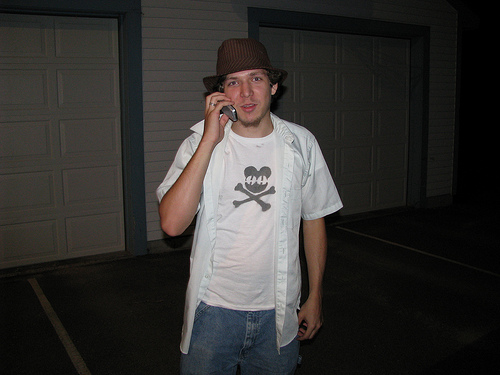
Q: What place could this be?
A: It is a garage.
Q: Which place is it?
A: It is a garage.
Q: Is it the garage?
A: Yes, it is the garage.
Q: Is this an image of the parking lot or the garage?
A: It is showing the garage.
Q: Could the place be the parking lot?
A: No, it is the garage.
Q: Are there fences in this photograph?
A: No, there are no fences.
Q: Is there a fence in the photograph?
A: No, there are no fences.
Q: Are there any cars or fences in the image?
A: No, there are no fences or cars.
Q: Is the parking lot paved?
A: Yes, the parking lot is paved.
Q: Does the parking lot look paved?
A: Yes, the parking lot is paved.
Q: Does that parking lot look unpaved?
A: No, the parking lot is paved.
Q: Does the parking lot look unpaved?
A: No, the parking lot is paved.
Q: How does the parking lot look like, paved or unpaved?
A: The parking lot is paved.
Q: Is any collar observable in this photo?
A: Yes, there is a collar.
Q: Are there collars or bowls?
A: Yes, there is a collar.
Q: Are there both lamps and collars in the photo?
A: No, there is a collar but no lamps.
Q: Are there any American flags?
A: No, there are no American flags.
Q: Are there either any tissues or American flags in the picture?
A: No, there are no American flags or tissues.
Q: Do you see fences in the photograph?
A: No, there are no fences.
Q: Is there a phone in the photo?
A: Yes, there is a phone.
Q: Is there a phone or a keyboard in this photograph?
A: Yes, there is a phone.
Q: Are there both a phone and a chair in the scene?
A: No, there is a phone but no chairs.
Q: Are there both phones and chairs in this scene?
A: No, there is a phone but no chairs.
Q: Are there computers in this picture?
A: No, there are no computers.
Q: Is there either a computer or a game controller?
A: No, there are no computers or game controllers.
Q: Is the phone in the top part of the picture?
A: Yes, the phone is in the top of the image.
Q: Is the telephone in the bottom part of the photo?
A: No, the telephone is in the top of the image.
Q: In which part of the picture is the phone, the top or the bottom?
A: The phone is in the top of the image.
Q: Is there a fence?
A: No, there are no fences.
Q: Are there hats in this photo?
A: Yes, there is a hat.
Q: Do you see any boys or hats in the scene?
A: Yes, there is a hat.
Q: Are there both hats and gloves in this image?
A: No, there is a hat but no gloves.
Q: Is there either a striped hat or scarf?
A: Yes, there is a striped hat.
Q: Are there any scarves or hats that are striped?
A: Yes, the hat is striped.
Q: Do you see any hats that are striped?
A: Yes, there is a striped hat.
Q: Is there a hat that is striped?
A: Yes, there is a hat that is striped.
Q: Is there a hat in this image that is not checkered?
A: Yes, there is a striped hat.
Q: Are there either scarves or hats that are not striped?
A: No, there is a hat but it is striped.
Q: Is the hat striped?
A: Yes, the hat is striped.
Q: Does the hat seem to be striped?
A: Yes, the hat is striped.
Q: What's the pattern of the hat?
A: The hat is striped.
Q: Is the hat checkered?
A: No, the hat is striped.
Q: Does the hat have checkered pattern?
A: No, the hat is striped.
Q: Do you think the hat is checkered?
A: No, the hat is striped.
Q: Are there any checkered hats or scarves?
A: No, there is a hat but it is striped.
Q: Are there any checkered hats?
A: No, there is a hat but it is striped.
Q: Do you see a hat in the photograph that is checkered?
A: No, there is a hat but it is striped.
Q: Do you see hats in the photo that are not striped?
A: No, there is a hat but it is striped.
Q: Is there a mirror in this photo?
A: No, there are no mirrors.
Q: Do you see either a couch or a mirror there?
A: No, there are no mirrors or couches.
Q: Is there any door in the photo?
A: Yes, there are doors.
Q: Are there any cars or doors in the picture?
A: Yes, there are doors.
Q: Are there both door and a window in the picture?
A: No, there are doors but no windows.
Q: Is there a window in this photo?
A: No, there are no windows.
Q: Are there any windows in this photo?
A: No, there are no windows.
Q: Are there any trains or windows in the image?
A: No, there are no windows or trains.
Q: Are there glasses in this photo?
A: No, there are no glasses.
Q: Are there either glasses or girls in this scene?
A: No, there are no glasses or girls.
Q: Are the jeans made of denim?
A: Yes, the jeans are made of denim.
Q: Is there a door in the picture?
A: Yes, there is a door.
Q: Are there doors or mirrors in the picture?
A: Yes, there is a door.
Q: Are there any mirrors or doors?
A: Yes, there is a door.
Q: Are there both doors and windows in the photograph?
A: No, there is a door but no windows.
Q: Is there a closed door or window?
A: Yes, there is a closed door.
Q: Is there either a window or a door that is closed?
A: Yes, the door is closed.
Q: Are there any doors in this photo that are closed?
A: Yes, there is a closed door.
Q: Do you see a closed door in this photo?
A: Yes, there is a closed door.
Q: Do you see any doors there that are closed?
A: Yes, there is a door that is closed.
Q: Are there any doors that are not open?
A: Yes, there is an closed door.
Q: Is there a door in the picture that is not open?
A: Yes, there is an closed door.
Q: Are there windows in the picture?
A: No, there are no windows.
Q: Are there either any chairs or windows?
A: No, there are no windows or chairs.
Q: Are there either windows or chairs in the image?
A: No, there are no windows or chairs.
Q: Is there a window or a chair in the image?
A: No, there are no windows or chairs.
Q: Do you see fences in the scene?
A: No, there are no fences.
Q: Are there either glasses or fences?
A: No, there are no fences or glasses.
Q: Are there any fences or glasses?
A: No, there are no fences or glasses.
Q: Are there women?
A: No, there are no women.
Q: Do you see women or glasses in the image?
A: No, there are no women or glasses.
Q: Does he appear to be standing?
A: Yes, the man is standing.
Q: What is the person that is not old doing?
A: The man is standing.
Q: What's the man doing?
A: The man is standing.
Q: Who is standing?
A: The man is standing.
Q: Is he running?
A: No, the man is standing.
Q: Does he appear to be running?
A: No, the man is standing.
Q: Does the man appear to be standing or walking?
A: The man is standing.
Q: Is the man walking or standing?
A: The man is standing.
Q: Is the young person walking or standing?
A: The man is standing.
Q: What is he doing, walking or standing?
A: The man is standing.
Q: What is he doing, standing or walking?
A: The man is standing.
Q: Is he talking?
A: Yes, the man is talking.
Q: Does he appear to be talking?
A: Yes, the man is talking.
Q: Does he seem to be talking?
A: Yes, the man is talking.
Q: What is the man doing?
A: The man is talking.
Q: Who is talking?
A: The man is talking.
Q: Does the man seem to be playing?
A: No, the man is talking.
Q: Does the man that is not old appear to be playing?
A: No, the man is talking.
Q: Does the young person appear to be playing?
A: No, the man is talking.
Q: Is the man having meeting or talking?
A: The man is talking.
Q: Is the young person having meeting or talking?
A: The man is talking.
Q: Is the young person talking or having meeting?
A: The man is talking.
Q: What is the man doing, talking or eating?
A: The man is talking.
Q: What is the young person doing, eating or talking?
A: The man is talking.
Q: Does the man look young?
A: Yes, the man is young.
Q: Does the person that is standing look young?
A: Yes, the man is young.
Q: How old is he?
A: The man is young.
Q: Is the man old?
A: No, the man is young.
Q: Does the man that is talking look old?
A: No, the man is young.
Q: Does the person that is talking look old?
A: No, the man is young.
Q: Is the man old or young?
A: The man is young.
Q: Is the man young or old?
A: The man is young.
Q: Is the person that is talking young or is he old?
A: The man is young.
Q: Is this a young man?
A: Yes, this is a young man.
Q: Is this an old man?
A: No, this is a young man.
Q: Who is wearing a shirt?
A: The man is wearing a shirt.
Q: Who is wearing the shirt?
A: The man is wearing a shirt.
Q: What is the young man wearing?
A: The man is wearing a shirt.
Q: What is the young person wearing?
A: The man is wearing a shirt.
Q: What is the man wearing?
A: The man is wearing a shirt.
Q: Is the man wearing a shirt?
A: Yes, the man is wearing a shirt.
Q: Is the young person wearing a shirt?
A: Yes, the man is wearing a shirt.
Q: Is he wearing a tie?
A: No, the man is wearing a shirt.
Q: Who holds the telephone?
A: The man holds the telephone.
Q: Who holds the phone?
A: The man holds the telephone.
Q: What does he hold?
A: The man holds the telephone.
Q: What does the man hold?
A: The man holds the telephone.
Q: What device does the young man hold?
A: The man holds the phone.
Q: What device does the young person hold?
A: The man holds the phone.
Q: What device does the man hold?
A: The man holds the phone.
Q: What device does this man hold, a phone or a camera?
A: The man holds a phone.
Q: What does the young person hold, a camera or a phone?
A: The man holds a phone.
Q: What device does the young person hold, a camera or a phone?
A: The man holds a phone.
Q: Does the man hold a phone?
A: Yes, the man holds a phone.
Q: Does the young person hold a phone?
A: Yes, the man holds a phone.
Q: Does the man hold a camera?
A: No, the man holds a phone.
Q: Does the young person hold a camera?
A: No, the man holds a phone.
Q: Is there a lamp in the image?
A: No, there are no lamps.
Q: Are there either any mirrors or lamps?
A: No, there are no lamps or mirrors.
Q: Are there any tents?
A: No, there are no tents.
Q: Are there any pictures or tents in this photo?
A: No, there are no tents or pictures.